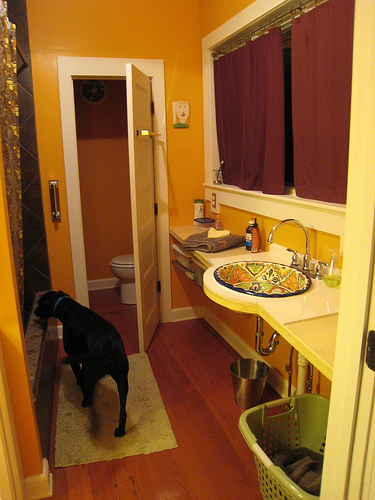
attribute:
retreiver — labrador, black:
[33, 284, 135, 434]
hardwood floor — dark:
[183, 373, 208, 458]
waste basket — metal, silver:
[228, 359, 268, 397]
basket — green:
[248, 410, 321, 435]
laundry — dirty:
[278, 447, 325, 482]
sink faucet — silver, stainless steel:
[269, 223, 312, 248]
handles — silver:
[289, 251, 327, 270]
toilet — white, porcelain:
[107, 251, 134, 307]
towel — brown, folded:
[187, 232, 225, 252]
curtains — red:
[221, 43, 347, 196]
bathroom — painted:
[17, 12, 375, 494]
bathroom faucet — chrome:
[267, 216, 327, 273]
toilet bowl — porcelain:
[110, 256, 135, 283]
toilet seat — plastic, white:
[118, 258, 130, 263]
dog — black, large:
[39, 292, 125, 387]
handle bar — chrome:
[46, 176, 62, 227]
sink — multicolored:
[225, 268, 302, 297]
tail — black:
[112, 369, 129, 396]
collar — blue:
[50, 296, 69, 310]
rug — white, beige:
[128, 409, 163, 455]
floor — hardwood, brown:
[176, 345, 207, 413]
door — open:
[130, 72, 164, 306]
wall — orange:
[136, 21, 183, 52]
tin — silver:
[230, 357, 262, 383]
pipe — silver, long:
[253, 321, 281, 360]